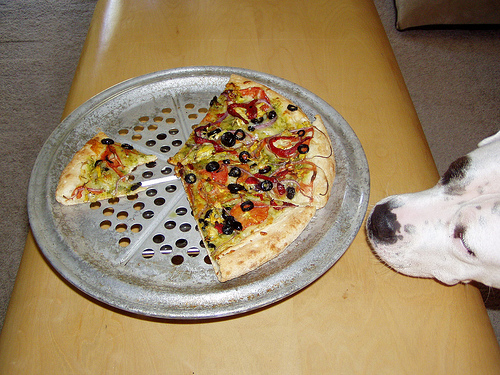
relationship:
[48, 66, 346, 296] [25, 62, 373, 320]
pizza lying on top of tray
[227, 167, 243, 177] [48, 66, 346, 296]
topping on pizza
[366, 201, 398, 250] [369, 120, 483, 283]
nose of a dog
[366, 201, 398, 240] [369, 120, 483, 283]
nose of a dog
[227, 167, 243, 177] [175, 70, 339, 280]
topping on a pizza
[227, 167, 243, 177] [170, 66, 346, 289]
topping on pizza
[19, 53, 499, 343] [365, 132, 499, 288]
close-up shows dog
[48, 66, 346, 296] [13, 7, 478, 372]
pizza on surface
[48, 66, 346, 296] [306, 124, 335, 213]
pizza has crust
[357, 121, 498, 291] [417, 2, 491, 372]
dog on right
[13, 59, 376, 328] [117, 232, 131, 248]
pan has whole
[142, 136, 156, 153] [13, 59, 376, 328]
whole in pan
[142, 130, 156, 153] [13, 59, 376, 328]
whole in pan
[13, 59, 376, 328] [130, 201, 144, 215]
pan has whole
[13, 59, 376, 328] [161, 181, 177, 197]
pan has whole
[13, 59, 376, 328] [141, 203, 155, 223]
pan has whole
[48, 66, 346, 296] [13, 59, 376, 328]
pizza on pan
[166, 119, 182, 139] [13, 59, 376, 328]
whole in pan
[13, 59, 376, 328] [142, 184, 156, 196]
pan has whole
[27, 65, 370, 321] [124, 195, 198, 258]
pan has holes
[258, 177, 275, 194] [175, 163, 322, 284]
olives on pizza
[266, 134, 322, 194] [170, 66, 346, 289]
onions on pizza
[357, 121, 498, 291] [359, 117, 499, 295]
dog has head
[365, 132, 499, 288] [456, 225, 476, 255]
dog has closed eyes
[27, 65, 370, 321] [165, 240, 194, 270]
pan has holes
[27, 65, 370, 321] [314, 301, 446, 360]
pan on table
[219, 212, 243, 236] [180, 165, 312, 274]
olives are on pizza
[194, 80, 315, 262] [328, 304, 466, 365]
pizza are on table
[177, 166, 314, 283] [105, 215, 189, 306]
pizza on tray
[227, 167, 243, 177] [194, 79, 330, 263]
topping on pizza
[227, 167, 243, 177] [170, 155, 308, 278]
topping on pizza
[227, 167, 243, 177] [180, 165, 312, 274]
topping on pizza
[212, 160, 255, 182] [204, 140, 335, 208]
topping on pizza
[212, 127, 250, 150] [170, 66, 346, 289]
topping on pizza